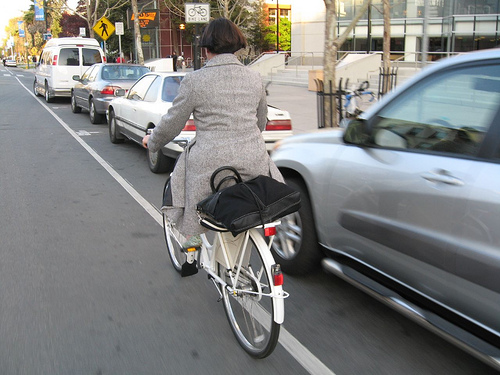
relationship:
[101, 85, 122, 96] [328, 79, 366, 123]
light on bike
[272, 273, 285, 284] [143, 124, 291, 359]
light on bicycle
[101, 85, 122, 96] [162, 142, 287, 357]
light on bike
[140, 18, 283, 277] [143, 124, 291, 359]
person riding bicycle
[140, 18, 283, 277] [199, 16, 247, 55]
person has hair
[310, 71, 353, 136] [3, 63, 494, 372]
black garbage-cans on road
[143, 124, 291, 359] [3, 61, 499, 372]
bicycle on street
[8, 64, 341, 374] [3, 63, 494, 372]
line painted on road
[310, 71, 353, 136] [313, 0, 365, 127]
black garbage-cans surrounding tree trunk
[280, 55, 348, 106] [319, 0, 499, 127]
stairs are next to building